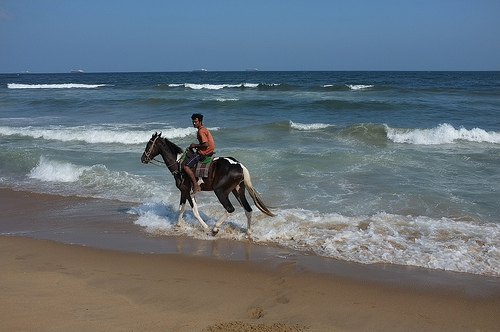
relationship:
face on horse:
[141, 127, 165, 165] [120, 115, 297, 247]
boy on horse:
[176, 104, 216, 199] [133, 124, 280, 248]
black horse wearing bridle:
[139, 131, 277, 237] [142, 132, 160, 163]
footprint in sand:
[273, 290, 294, 308] [3, 186, 497, 330]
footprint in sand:
[245, 304, 267, 320] [3, 186, 497, 330]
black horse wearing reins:
[139, 131, 277, 237] [141, 151, 171, 170]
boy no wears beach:
[183, 113, 215, 194] [0, 211, 442, 329]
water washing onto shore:
[0, 67, 498, 275] [10, 176, 499, 327]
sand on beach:
[71, 267, 146, 310] [213, 283, 288, 323]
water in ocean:
[0, 72, 497, 275] [0, 72, 498, 272]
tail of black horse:
[234, 160, 275, 213] [139, 131, 277, 237]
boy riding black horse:
[183, 113, 215, 194] [139, 131, 277, 237]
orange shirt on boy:
[195, 125, 213, 155] [183, 113, 215, 194]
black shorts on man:
[183, 150, 200, 174] [181, 100, 221, 205]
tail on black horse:
[238, 163, 274, 217] [139, 131, 277, 237]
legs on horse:
[168, 197, 260, 235] [137, 136, 259, 223]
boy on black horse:
[183, 113, 215, 194] [139, 131, 277, 237]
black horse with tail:
[139, 131, 277, 237] [244, 170, 274, 220]